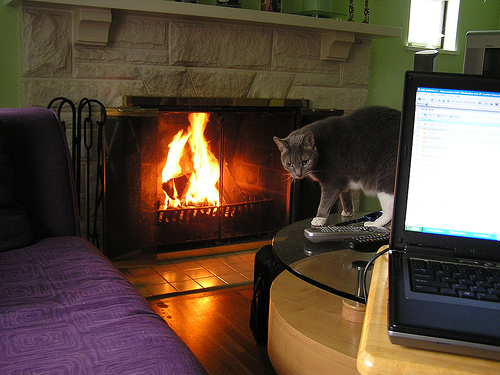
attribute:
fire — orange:
[163, 127, 228, 196]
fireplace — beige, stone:
[126, 108, 309, 262]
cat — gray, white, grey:
[270, 106, 402, 227]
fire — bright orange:
[159, 110, 225, 212]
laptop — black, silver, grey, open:
[387, 68, 498, 361]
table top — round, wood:
[265, 249, 359, 372]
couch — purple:
[0, 103, 210, 370]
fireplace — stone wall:
[120, 97, 310, 256]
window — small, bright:
[401, 0, 463, 52]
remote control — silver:
[302, 221, 385, 243]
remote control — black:
[345, 231, 390, 250]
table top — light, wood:
[356, 248, 493, 370]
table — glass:
[269, 210, 389, 302]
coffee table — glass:
[263, 209, 393, 372]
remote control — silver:
[304, 223, 391, 243]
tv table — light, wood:
[356, 240, 498, 373]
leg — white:
[357, 190, 396, 229]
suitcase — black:
[250, 240, 285, 347]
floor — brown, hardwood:
[203, 284, 255, 373]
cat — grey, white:
[272, 102, 395, 233]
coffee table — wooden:
[255, 203, 376, 373]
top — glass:
[265, 203, 387, 293]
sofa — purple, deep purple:
[1, 106, 219, 372]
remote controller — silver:
[307, 222, 388, 245]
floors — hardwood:
[163, 300, 257, 370]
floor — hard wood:
[179, 305, 239, 347]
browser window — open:
[416, 93, 487, 220]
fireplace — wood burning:
[145, 104, 291, 245]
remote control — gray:
[303, 223, 390, 240]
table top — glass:
[272, 215, 392, 302]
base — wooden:
[268, 245, 376, 371]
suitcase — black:
[253, 242, 288, 354]